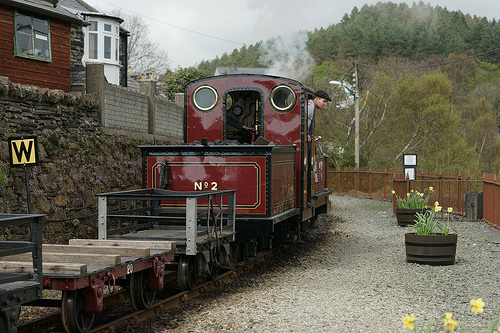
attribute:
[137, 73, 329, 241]
train — red, black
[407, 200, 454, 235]
daffodil — yellow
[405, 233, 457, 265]
planter — wooden, brown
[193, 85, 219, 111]
window — round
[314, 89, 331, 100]
hat — black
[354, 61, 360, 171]
pole — wooden, brown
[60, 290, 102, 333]
wheel — metal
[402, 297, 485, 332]
flower — yellow, blooming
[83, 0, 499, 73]
sky — gray, cloudy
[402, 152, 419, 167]
frame — black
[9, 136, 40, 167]
sign — yellow, black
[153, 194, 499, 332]
path — gravel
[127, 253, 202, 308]
wheels — rusty